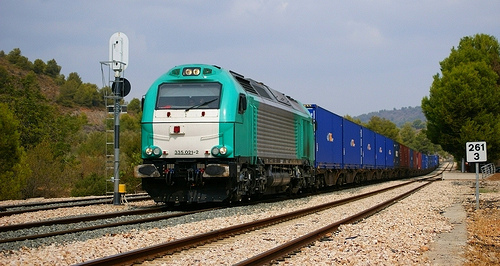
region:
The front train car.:
[141, 65, 314, 206]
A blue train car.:
[312, 104, 345, 186]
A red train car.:
[398, 140, 410, 175]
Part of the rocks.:
[371, 223, 398, 257]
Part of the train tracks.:
[199, 220, 282, 264]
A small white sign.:
[466, 142, 486, 162]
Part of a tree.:
[25, 107, 59, 148]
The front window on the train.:
[155, 79, 222, 110]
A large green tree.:
[423, 35, 498, 171]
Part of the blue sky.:
[291, 44, 341, 86]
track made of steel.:
[185, 228, 231, 253]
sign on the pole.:
[463, 140, 485, 161]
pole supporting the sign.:
[473, 170, 480, 209]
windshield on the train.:
[162, 90, 201, 100]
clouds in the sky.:
[275, 7, 347, 33]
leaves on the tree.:
[41, 120, 59, 145]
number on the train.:
[170, 143, 200, 160]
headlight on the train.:
[203, 144, 229, 159]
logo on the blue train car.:
[323, 130, 335, 146]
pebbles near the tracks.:
[107, 227, 156, 251]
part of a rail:
[416, 192, 418, 196]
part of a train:
[304, 83, 314, 118]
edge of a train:
[314, 147, 316, 156]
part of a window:
[203, 103, 213, 116]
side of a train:
[318, 158, 327, 175]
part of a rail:
[374, 200, 381, 220]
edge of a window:
[338, 104, 342, 118]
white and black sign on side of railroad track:
[462, 139, 486, 211]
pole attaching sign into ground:
[474, 163, 487, 213]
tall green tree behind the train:
[433, 38, 499, 151]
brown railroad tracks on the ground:
[117, 201, 342, 262]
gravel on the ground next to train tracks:
[373, 213, 414, 263]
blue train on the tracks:
[133, 63, 438, 203]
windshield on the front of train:
[147, 81, 222, 106]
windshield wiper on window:
[186, 96, 222, 109]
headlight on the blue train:
[208, 144, 226, 155]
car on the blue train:
[310, 107, 348, 166]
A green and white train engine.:
[130, 56, 313, 200]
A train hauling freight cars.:
[125, 53, 443, 200]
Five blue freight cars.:
[308, 97, 395, 177]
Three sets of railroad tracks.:
[6, 178, 448, 264]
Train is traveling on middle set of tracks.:
[133, 53, 450, 215]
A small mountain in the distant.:
[348, 90, 460, 148]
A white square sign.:
[461, 135, 492, 165]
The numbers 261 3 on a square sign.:
[463, 136, 491, 168]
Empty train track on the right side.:
[163, 188, 470, 261]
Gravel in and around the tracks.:
[6, 174, 466, 264]